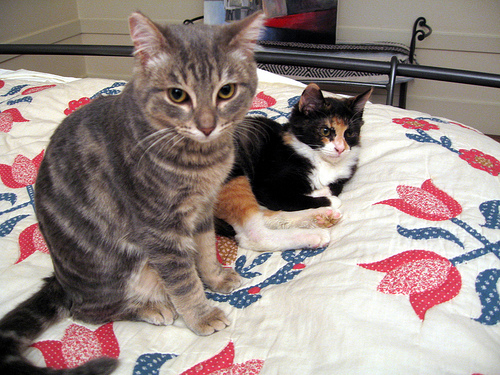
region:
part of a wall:
[438, 0, 480, 40]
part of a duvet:
[332, 270, 404, 318]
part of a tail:
[21, 298, 62, 332]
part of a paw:
[193, 292, 247, 350]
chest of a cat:
[209, 207, 230, 216]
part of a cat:
[322, 127, 360, 171]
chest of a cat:
[181, 149, 219, 203]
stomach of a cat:
[63, 156, 114, 218]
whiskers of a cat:
[136, 130, 181, 167]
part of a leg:
[233, 215, 295, 255]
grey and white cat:
[66, 29, 274, 366]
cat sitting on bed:
[57, 19, 235, 369]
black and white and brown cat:
[172, 64, 368, 229]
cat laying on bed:
[200, 91, 406, 265]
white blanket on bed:
[83, 117, 498, 373]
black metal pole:
[226, 28, 479, 93]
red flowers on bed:
[384, 131, 492, 320]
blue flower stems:
[189, 239, 369, 324]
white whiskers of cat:
[115, 84, 312, 204]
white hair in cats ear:
[125, 22, 207, 50]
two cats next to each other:
[16, 9, 390, 341]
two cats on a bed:
[7, 17, 436, 289]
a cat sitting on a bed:
[16, 3, 251, 345]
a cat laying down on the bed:
[197, 42, 454, 255]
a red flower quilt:
[362, 155, 497, 345]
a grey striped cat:
[3, 10, 278, 359]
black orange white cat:
[215, 56, 427, 281]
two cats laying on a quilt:
[16, 2, 428, 352]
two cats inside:
[30, 13, 424, 353]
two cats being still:
[23, 10, 417, 340]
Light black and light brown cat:
[0, 15, 255, 372]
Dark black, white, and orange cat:
[219, 81, 376, 267]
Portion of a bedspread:
[367, 101, 499, 373]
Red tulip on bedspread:
[356, 242, 466, 322]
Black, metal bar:
[1, 30, 130, 67]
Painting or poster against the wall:
[201, 0, 342, 44]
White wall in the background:
[11, 0, 114, 40]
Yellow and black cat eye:
[166, 84, 191, 108]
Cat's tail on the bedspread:
[0, 280, 120, 371]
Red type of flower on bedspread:
[448, 143, 498, 174]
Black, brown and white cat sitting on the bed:
[32, 5, 262, 340]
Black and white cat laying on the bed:
[235, 78, 365, 206]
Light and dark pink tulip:
[355, 247, 461, 323]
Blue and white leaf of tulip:
[390, 221, 466, 251]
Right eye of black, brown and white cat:
[160, 81, 195, 111]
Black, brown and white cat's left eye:
[215, 75, 241, 101]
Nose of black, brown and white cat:
[190, 105, 225, 140]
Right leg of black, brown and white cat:
[142, 240, 203, 316]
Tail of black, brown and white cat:
[3, 270, 65, 366]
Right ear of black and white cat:
[295, 77, 333, 122]